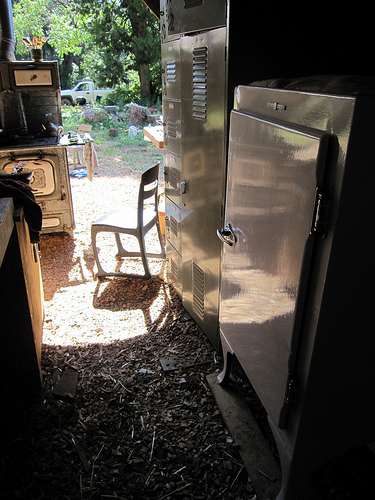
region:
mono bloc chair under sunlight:
[88, 163, 169, 288]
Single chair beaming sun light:
[85, 164, 163, 277]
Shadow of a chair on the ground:
[93, 275, 160, 337]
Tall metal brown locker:
[180, 26, 220, 346]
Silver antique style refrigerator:
[214, 79, 359, 435]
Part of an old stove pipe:
[1, 1, 16, 61]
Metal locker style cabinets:
[159, 38, 180, 291]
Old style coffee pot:
[37, 111, 60, 139]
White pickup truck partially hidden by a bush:
[58, 80, 130, 105]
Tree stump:
[127, 101, 147, 125]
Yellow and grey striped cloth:
[83, 137, 100, 182]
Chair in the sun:
[74, 151, 185, 288]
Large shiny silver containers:
[149, 0, 340, 420]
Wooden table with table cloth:
[61, 121, 107, 175]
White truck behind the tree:
[57, 72, 134, 115]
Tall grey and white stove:
[5, 5, 88, 243]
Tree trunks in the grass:
[81, 93, 157, 138]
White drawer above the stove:
[5, 59, 69, 96]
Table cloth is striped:
[77, 137, 109, 192]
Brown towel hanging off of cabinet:
[5, 171, 55, 251]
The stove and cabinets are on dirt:
[31, 132, 239, 408]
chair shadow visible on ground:
[86, 274, 161, 339]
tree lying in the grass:
[87, 78, 118, 129]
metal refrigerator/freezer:
[211, 98, 324, 381]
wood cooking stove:
[12, 82, 91, 220]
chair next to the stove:
[110, 135, 173, 290]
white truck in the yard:
[71, 75, 136, 115]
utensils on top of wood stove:
[15, 21, 63, 61]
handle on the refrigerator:
[206, 221, 255, 258]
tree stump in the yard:
[126, 95, 158, 144]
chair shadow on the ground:
[108, 258, 164, 333]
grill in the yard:
[67, 89, 94, 111]